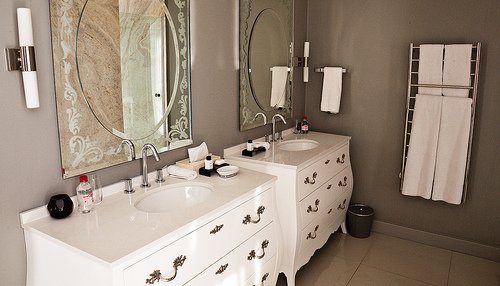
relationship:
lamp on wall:
[10, 0, 47, 117] [333, 24, 410, 104]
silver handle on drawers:
[242, 205, 266, 225] [141, 150, 364, 285]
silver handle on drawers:
[142, 253, 187, 284] [141, 150, 364, 285]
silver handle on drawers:
[244, 239, 270, 262] [141, 150, 364, 285]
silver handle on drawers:
[305, 171, 319, 187] [141, 150, 364, 285]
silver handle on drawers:
[305, 201, 320, 213] [141, 150, 364, 285]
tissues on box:
[188, 140, 208, 161] [175, 153, 221, 175]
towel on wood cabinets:
[432, 94, 473, 207] [389, 33, 479, 211]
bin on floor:
[347, 203, 374, 238] [334, 248, 449, 283]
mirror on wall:
[44, 0, 199, 176] [1, 2, 311, 249]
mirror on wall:
[236, 1, 294, 132] [336, 19, 421, 111]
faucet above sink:
[139, 140, 163, 189] [129, 177, 219, 217]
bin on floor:
[348, 202, 377, 234] [319, 240, 494, 280]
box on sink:
[163, 152, 202, 190] [107, 120, 219, 238]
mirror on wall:
[44, 0, 199, 176] [1, 1, 308, 284]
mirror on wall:
[237, 1, 294, 131] [1, 1, 308, 284]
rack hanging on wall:
[397, 42, 481, 195] [303, 2, 483, 254]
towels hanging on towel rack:
[403, 41, 474, 199] [399, 38, 480, 207]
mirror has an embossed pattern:
[44, 0, 199, 176] [54, 1, 109, 174]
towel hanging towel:
[442, 45, 472, 95] [417, 43, 443, 93]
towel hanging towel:
[429, 94, 476, 204] [417, 43, 443, 93]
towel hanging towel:
[399, 92, 444, 202] [417, 43, 443, 93]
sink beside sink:
[38, 157, 268, 257] [218, 113, 351, 194]